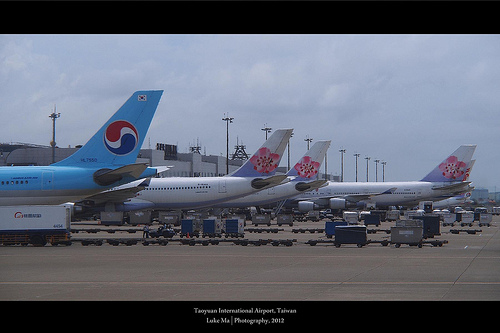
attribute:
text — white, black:
[190, 303, 302, 328]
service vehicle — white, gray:
[1, 201, 76, 251]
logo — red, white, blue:
[103, 117, 140, 154]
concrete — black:
[260, 247, 395, 288]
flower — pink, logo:
[239, 142, 284, 177]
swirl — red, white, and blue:
[96, 117, 146, 154]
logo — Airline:
[100, 118, 142, 158]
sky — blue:
[1, 34, 499, 189]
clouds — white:
[17, 57, 84, 107]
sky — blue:
[43, 41, 111, 69]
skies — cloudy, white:
[1, 35, 498, 192]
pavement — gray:
[21, 249, 472, 298]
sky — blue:
[80, 46, 498, 193]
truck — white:
[2, 200, 78, 244]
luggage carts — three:
[176, 213, 254, 242]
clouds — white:
[182, 50, 453, 138]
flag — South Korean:
[126, 86, 156, 109]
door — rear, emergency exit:
[215, 179, 227, 200]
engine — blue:
[83, 189, 161, 237]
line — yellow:
[276, 244, 388, 302]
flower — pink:
[244, 148, 288, 180]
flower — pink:
[290, 139, 318, 176]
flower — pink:
[428, 140, 466, 180]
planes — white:
[188, 117, 292, 228]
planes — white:
[284, 131, 344, 187]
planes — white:
[348, 124, 476, 214]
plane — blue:
[36, 70, 182, 230]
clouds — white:
[220, 42, 370, 123]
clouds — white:
[238, 58, 365, 128]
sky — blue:
[215, 58, 414, 151]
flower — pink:
[251, 142, 273, 172]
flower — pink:
[294, 157, 319, 177]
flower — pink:
[442, 154, 465, 179]